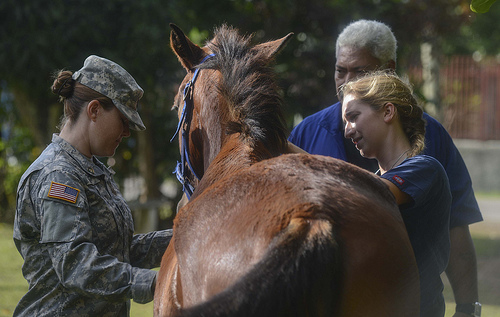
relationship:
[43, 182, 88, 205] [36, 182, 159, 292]
flag on arm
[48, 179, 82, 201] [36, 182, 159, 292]
patch on arm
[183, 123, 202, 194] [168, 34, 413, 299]
reins on horse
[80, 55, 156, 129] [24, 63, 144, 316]
hat on woman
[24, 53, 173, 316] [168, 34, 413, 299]
woman around horse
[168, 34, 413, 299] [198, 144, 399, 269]
horse has wintercoat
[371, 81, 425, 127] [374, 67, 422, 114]
woman with braid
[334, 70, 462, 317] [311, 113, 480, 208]
woman wearing blue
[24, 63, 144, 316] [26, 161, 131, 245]
woman has uniform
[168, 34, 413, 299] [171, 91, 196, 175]
horse wearing bridle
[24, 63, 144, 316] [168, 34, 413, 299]
woman caring horse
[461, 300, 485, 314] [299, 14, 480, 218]
watch on man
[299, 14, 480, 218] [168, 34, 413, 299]
man standing beside horse